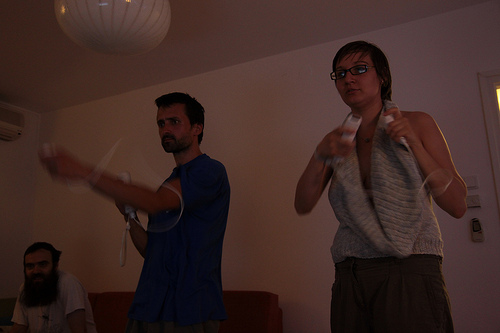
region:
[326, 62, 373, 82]
The glasses on the woman's face.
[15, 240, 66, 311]
A man with a long beard sitting down.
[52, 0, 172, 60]
A light fixture hanging from the ceiling.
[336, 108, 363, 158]
A Wii controller in the woman's right hand.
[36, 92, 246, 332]
A man in a blue shirt using a Wii controller.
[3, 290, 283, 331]
The couch behind the man in the blue shirt.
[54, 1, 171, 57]
the round white object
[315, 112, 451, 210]
the white wii controllers and wire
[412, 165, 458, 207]
the white wire for the wii controls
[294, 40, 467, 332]
the woman holding the wii controllers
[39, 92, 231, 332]
the man holding the wii controllers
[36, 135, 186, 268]
the white wii controllers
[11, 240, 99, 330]
the man is sitting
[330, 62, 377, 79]
the dark rimmed glasses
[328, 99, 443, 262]
the sleeveless gray sweater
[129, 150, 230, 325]
the black short sleeved shirt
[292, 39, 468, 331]
Dark haired woman with black glasses.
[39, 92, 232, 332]
Black haired man in blue shirt.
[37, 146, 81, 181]
Blue shirt man's left hand.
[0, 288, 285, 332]
Red couch in a room.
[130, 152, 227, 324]
Blue t-shirt on a man.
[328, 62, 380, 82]
Black glasses on a woman's face.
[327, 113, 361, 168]
The longer white wii remote in a woman's right hand.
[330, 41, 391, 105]
Short brown hair on a woman.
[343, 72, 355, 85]
Nose of a woman.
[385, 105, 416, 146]
A woman's left hand.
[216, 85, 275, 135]
pink color on the wall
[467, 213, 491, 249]
outlet on the wall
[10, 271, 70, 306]
long black beard on man's face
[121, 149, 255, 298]
short sleeve blue shirt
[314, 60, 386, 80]
glasses on person's face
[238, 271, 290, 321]
edge of brown sofa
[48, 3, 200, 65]
large white light in ceiling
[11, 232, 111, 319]
man sitting on sofa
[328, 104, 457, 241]
white video game controller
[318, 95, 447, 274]
grey cowl neck sweater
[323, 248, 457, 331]
pair of brown pants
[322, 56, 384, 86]
black framed glasses on woman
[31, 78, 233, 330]
man in t-shirt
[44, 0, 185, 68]
white light covering on ceiling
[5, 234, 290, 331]
man in beard sitting on couch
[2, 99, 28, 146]
vent at top of wall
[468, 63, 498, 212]
door frame behind woman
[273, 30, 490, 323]
girl playing a Wii game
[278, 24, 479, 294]
woman playing the Wii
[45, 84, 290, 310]
guy playing a Will game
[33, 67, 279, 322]
man playing the Wii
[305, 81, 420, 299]
A woman with a very low cut sweater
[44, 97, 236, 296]
Man playing a videogame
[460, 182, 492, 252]
light switches on the wall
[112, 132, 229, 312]
A man with a blue shirt on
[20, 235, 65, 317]
A man with a very long beard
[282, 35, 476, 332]
young brunette adult female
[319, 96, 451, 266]
ladies gray knit sweater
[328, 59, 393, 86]
black eyeglasses on woman's face